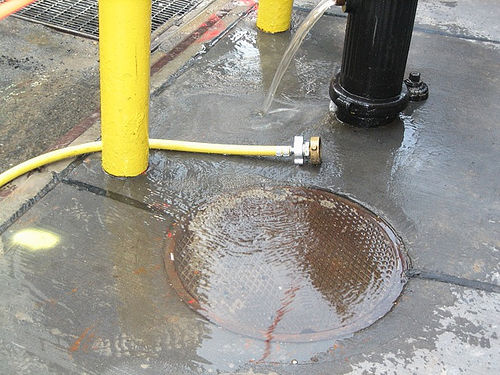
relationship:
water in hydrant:
[258, 1, 338, 116] [321, 6, 417, 113]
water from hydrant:
[258, 1, 338, 116] [321, 6, 417, 113]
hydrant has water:
[321, 6, 417, 113] [258, 1, 338, 116]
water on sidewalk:
[258, 1, 338, 116] [15, 1, 487, 363]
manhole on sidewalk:
[157, 188, 449, 355] [15, 1, 487, 363]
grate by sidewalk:
[5, 2, 197, 72] [15, 1, 487, 363]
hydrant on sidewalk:
[321, 6, 417, 113] [15, 1, 487, 363]